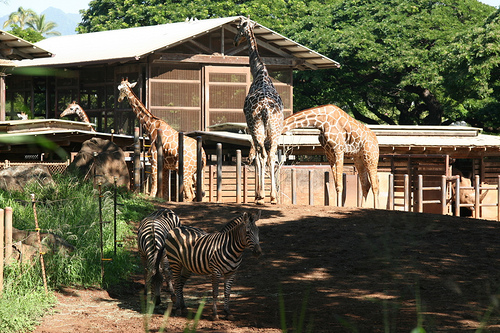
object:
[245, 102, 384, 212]
giraffe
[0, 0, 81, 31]
sun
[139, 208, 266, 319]
zebra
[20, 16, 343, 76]
roof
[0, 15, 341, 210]
building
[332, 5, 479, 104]
trees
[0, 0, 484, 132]
background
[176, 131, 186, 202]
pole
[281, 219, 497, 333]
ground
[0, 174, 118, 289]
fence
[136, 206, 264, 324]
animals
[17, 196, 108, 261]
grass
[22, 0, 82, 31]
sky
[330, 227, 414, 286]
dirt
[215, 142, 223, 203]
post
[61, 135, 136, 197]
rock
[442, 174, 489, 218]
rhinoceros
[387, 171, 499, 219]
pen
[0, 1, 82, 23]
range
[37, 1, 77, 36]
mountains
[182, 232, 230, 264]
fur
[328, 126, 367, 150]
fur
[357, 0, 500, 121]
group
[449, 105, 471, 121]
leaves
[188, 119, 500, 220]
shed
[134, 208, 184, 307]
zebras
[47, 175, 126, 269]
section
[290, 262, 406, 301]
patch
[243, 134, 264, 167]
head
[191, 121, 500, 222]
barn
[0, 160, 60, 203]
rocks